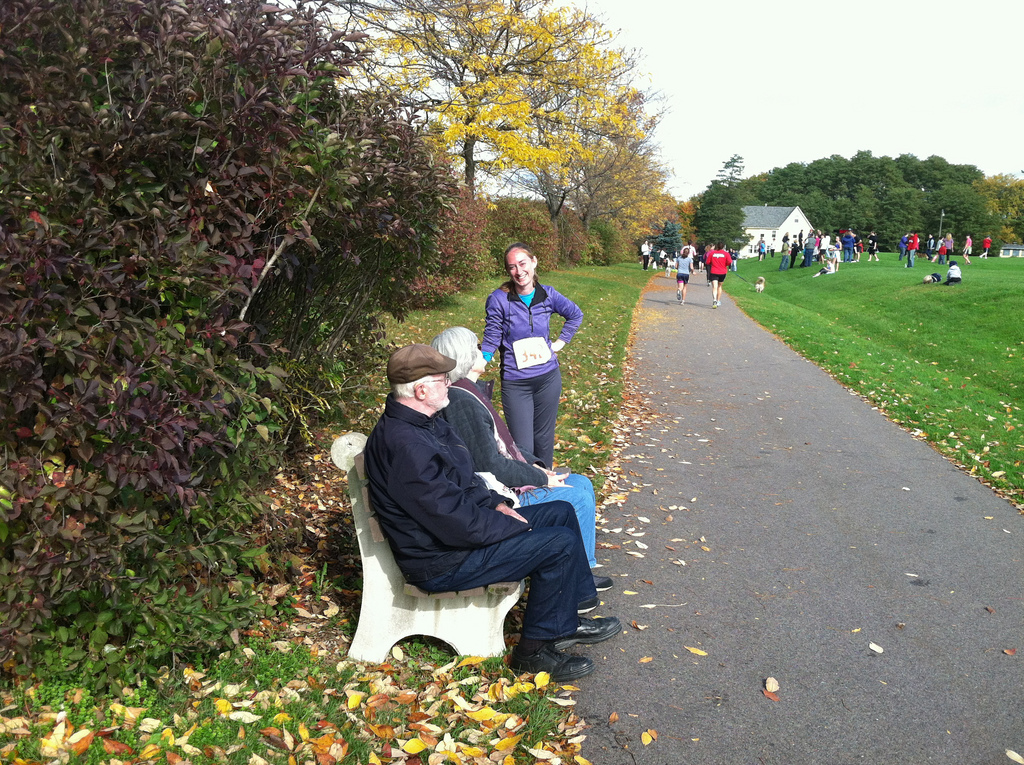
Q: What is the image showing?
A: It is showing a park.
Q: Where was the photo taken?
A: It was taken at the park.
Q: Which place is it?
A: It is a park.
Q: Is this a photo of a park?
A: Yes, it is showing a park.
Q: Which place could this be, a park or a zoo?
A: It is a park.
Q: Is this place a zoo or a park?
A: It is a park.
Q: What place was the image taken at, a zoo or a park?
A: It was taken at a park.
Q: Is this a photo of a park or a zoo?
A: It is showing a park.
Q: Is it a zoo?
A: No, it is a park.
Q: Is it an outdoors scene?
A: Yes, it is outdoors.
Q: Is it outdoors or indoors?
A: It is outdoors.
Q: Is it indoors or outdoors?
A: It is outdoors.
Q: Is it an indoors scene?
A: No, it is outdoors.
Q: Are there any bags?
A: No, there are no bags.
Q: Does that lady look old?
A: Yes, the lady is old.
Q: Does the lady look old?
A: Yes, the lady is old.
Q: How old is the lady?
A: The lady is old.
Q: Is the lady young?
A: No, the lady is old.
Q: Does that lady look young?
A: No, the lady is old.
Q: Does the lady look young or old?
A: The lady is old.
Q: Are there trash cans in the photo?
A: No, there are no trash cans.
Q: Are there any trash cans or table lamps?
A: No, there are no trash cans or table lamps.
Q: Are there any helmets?
A: No, there are no helmets.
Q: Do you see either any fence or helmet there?
A: No, there are no helmets or fences.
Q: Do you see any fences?
A: No, there are no fences.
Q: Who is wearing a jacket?
A: The man is wearing a jacket.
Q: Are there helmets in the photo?
A: No, there are no helmets.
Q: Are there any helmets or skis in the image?
A: No, there are no helmets or skis.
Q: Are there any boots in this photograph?
A: Yes, there are boots.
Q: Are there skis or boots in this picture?
A: Yes, there are boots.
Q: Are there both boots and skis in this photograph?
A: No, there are boots but no skis.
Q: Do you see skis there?
A: No, there are no skis.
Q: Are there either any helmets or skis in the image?
A: No, there are no skis or helmets.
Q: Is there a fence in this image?
A: No, there are no fences.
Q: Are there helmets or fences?
A: No, there are no fences or helmets.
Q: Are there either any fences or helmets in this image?
A: No, there are no fences or helmets.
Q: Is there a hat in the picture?
A: Yes, there is a hat.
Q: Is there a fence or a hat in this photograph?
A: Yes, there is a hat.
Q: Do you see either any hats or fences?
A: Yes, there is a hat.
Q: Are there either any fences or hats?
A: Yes, there is a hat.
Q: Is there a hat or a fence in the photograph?
A: Yes, there is a hat.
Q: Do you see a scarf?
A: No, there are no scarves.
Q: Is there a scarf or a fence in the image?
A: No, there are no scarves or fences.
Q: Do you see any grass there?
A: Yes, there is grass.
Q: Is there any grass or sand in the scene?
A: Yes, there is grass.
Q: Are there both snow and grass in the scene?
A: No, there is grass but no snow.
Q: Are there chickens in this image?
A: No, there are no chickens.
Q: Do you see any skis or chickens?
A: No, there are no chickens or skis.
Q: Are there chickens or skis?
A: No, there are no chickens or skis.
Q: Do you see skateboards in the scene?
A: No, there are no skateboards.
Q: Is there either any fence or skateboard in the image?
A: No, there are no skateboards or fences.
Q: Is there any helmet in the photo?
A: No, there are no helmets.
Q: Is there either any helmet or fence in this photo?
A: No, there are no helmets or fences.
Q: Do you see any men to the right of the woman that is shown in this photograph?
A: Yes, there is a man to the right of the woman.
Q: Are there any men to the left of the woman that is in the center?
A: No, the man is to the right of the woman.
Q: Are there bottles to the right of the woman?
A: No, there is a man to the right of the woman.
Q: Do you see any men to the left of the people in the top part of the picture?
A: Yes, there is a man to the left of the people.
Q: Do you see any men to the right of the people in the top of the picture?
A: No, the man is to the left of the people.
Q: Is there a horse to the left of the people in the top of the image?
A: No, there is a man to the left of the people.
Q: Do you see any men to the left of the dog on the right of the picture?
A: Yes, there is a man to the left of the dog.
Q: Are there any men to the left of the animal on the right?
A: Yes, there is a man to the left of the dog.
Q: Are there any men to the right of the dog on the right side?
A: No, the man is to the left of the dog.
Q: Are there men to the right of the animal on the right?
A: No, the man is to the left of the dog.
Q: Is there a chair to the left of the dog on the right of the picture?
A: No, there is a man to the left of the dog.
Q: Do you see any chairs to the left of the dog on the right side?
A: No, there is a man to the left of the dog.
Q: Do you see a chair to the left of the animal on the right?
A: No, there is a man to the left of the dog.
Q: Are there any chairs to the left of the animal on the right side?
A: No, there is a man to the left of the dog.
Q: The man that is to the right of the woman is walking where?
A: The man is walking in the park.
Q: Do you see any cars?
A: No, there are no cars.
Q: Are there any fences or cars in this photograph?
A: No, there are no cars or fences.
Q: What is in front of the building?
A: The trees are in front of the building.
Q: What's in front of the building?
A: The trees are in front of the building.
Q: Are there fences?
A: No, there are no fences.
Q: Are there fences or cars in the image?
A: No, there are no fences or cars.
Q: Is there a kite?
A: No, there are no kites.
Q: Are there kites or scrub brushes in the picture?
A: No, there are no kites or scrub brushes.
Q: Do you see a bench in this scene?
A: Yes, there is a bench.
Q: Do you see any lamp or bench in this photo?
A: Yes, there is a bench.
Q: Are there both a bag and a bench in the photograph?
A: No, there is a bench but no bags.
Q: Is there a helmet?
A: No, there are no helmets.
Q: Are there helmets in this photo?
A: No, there are no helmets.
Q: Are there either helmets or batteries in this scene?
A: No, there are no helmets or batteries.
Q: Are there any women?
A: Yes, there is a woman.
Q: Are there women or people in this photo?
A: Yes, there is a woman.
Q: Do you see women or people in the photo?
A: Yes, there is a woman.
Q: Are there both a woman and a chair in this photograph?
A: No, there is a woman but no chairs.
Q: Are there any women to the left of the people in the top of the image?
A: Yes, there is a woman to the left of the people.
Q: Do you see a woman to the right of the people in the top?
A: No, the woman is to the left of the people.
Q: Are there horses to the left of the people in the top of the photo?
A: No, there is a woman to the left of the people.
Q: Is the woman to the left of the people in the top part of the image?
A: Yes, the woman is to the left of the people.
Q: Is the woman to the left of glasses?
A: No, the woman is to the left of the people.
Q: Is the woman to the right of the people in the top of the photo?
A: No, the woman is to the left of the people.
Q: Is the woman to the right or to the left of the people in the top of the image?
A: The woman is to the left of the people.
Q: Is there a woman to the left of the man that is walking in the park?
A: Yes, there is a woman to the left of the man.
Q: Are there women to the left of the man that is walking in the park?
A: Yes, there is a woman to the left of the man.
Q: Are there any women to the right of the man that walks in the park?
A: No, the woman is to the left of the man.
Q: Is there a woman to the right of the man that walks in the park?
A: No, the woman is to the left of the man.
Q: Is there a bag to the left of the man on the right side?
A: No, there is a woman to the left of the man.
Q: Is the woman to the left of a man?
A: Yes, the woman is to the left of a man.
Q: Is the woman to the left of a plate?
A: No, the woman is to the left of a man.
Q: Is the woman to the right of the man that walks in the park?
A: No, the woman is to the left of the man.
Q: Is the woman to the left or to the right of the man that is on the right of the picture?
A: The woman is to the left of the man.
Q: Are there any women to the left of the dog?
A: Yes, there is a woman to the left of the dog.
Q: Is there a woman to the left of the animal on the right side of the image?
A: Yes, there is a woman to the left of the dog.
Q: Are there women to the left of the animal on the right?
A: Yes, there is a woman to the left of the dog.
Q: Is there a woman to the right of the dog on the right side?
A: No, the woman is to the left of the dog.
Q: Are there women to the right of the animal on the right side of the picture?
A: No, the woman is to the left of the dog.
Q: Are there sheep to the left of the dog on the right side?
A: No, there is a woman to the left of the dog.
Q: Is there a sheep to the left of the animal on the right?
A: No, there is a woman to the left of the dog.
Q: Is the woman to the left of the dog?
A: Yes, the woman is to the left of the dog.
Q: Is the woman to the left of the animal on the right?
A: Yes, the woman is to the left of the dog.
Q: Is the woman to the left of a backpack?
A: No, the woman is to the left of the dog.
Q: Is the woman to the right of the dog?
A: No, the woman is to the left of the dog.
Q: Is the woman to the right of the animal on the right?
A: No, the woman is to the left of the dog.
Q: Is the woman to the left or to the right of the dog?
A: The woman is to the left of the dog.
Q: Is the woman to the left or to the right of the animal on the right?
A: The woman is to the left of the dog.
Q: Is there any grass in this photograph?
A: Yes, there is grass.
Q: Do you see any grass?
A: Yes, there is grass.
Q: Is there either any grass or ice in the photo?
A: Yes, there is grass.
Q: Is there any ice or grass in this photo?
A: Yes, there is grass.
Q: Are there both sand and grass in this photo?
A: No, there is grass but no sand.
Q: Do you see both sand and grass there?
A: No, there is grass but no sand.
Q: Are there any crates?
A: No, there are no crates.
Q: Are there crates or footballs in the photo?
A: No, there are no crates or footballs.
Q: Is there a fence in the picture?
A: No, there are no fences.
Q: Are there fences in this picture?
A: No, there are no fences.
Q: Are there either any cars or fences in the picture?
A: No, there are no fences or cars.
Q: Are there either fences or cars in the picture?
A: No, there are no fences or cars.